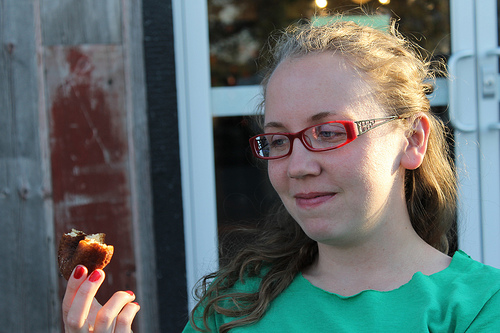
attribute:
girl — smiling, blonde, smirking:
[61, 22, 500, 332]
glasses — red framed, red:
[248, 115, 404, 160]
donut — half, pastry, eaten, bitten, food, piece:
[57, 228, 115, 282]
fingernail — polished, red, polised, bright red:
[72, 264, 86, 279]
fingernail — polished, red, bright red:
[89, 270, 103, 284]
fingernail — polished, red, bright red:
[124, 289, 135, 296]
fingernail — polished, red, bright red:
[131, 301, 141, 306]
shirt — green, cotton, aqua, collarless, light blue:
[182, 247, 499, 333]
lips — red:
[292, 190, 340, 210]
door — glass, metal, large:
[173, 0, 500, 333]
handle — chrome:
[484, 47, 500, 134]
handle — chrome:
[445, 48, 477, 134]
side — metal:
[356, 116, 406, 137]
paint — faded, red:
[40, 43, 138, 333]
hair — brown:
[183, 2, 466, 331]